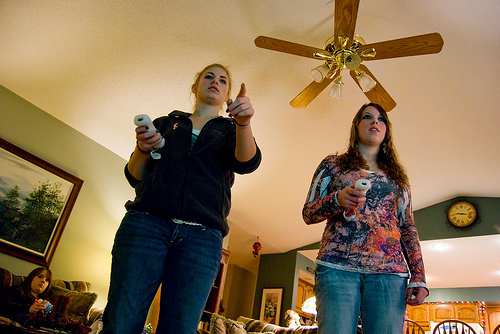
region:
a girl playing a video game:
[93, 60, 260, 329]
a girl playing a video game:
[300, 98, 428, 331]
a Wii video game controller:
[352, 177, 370, 196]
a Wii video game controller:
[130, 110, 162, 149]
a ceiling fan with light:
[253, 0, 443, 121]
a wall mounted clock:
[447, 197, 480, 229]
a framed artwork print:
[257, 283, 284, 326]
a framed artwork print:
[0, 136, 86, 266]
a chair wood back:
[431, 318, 476, 331]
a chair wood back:
[402, 316, 424, 331]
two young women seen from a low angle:
[93, 53, 433, 333]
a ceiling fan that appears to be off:
[249, 1, 447, 113]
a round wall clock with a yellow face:
[440, 194, 482, 233]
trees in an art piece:
[1, 135, 84, 258]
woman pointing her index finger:
[223, 77, 258, 130]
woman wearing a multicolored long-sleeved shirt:
[301, 97, 432, 292]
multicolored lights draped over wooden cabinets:
[401, 299, 488, 326]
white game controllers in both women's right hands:
[131, 111, 373, 212]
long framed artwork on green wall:
[251, 250, 296, 326]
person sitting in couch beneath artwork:
[1, 138, 95, 328]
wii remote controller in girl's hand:
[105, 104, 172, 152]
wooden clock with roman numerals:
[436, 191, 483, 243]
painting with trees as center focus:
[3, 167, 79, 246]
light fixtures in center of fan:
[313, 58, 390, 92]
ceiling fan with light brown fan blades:
[243, 5, 439, 104]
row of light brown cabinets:
[435, 292, 497, 321]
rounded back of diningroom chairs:
[435, 302, 487, 332]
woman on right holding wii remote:
[352, 177, 384, 228]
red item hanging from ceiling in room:
[250, 233, 277, 276]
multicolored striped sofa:
[223, 309, 275, 331]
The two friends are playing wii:
[128, 65, 449, 275]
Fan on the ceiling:
[255, 8, 442, 108]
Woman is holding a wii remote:
[113, 102, 173, 169]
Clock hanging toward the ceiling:
[429, 176, 493, 256]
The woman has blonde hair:
[167, 52, 268, 141]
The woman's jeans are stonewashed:
[302, 240, 391, 327]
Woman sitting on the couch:
[4, 255, 79, 332]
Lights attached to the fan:
[293, 50, 384, 95]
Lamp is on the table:
[283, 280, 339, 320]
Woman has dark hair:
[334, 108, 431, 223]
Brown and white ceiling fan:
[239, 0, 456, 135]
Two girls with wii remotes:
[98, 47, 439, 239]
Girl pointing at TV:
[111, 47, 283, 330]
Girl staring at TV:
[306, 87, 460, 322]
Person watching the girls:
[3, 235, 108, 326]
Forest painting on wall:
[3, 143, 91, 268]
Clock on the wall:
[424, 167, 492, 239]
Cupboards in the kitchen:
[291, 252, 496, 332]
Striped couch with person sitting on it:
[0, 240, 125, 331]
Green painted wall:
[4, 68, 441, 257]